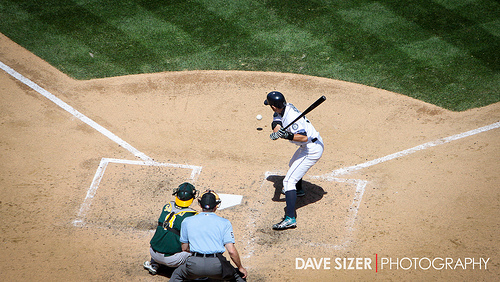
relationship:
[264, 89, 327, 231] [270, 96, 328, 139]
man swinging bat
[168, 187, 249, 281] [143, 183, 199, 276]
umpire behind player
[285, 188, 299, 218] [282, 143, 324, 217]
sock on leg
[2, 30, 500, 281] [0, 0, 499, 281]
sand on field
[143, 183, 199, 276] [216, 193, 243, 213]
catcher behind home plate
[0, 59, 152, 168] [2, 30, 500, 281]
line in sand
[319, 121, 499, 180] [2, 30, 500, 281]
line in sand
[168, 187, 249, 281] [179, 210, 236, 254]
umpire wearing shirt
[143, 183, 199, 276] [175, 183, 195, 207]
player wearing hat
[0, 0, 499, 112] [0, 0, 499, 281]
grass on field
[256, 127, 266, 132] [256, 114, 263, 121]
shadow under baseball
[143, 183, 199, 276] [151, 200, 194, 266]
player wearing uniform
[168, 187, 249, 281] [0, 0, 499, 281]
umpire on field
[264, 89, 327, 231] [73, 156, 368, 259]
man in batter's box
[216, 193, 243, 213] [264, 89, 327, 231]
home plate in front of man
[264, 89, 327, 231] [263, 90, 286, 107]
man wearing helmet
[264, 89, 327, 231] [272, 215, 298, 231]
man wearing shoe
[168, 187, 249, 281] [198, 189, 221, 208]
umpire wearing protective gear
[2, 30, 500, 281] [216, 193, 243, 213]
sand under home plate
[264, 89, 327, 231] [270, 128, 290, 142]
man wearing gloves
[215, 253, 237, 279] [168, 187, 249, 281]
ball pouch on umpire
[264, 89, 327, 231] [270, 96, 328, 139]
man holding bat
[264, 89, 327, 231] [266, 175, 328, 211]
man casting shadow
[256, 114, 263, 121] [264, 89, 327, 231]
baseball in front of man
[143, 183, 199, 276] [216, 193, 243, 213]
player behind home plate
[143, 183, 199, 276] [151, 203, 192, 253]
player wearing shirt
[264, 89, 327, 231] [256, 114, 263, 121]
man watching baseball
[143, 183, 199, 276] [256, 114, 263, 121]
player watching baseball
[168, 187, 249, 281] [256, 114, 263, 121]
umpire watching baseball